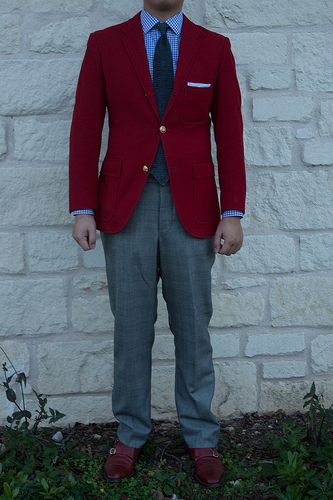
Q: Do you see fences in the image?
A: No, there are no fences.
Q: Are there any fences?
A: No, there are no fences.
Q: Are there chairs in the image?
A: No, there are no chairs.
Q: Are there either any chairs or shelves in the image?
A: No, there are no chairs or shelves.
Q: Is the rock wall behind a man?
A: Yes, the wall is behind a man.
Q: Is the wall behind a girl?
A: No, the wall is behind a man.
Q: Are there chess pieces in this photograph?
A: No, there are no chess pieces.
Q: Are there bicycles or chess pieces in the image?
A: No, there are no chess pieces or bicycles.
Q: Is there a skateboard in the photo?
A: No, there are no skateboards.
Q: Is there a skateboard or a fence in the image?
A: No, there are no skateboards or fences.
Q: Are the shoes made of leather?
A: Yes, the shoes are made of leather.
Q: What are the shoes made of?
A: The shoes are made of leather.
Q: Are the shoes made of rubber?
A: No, the shoes are made of leather.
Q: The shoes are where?
A: The shoes are on the ground.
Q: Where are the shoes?
A: The shoes are on the ground.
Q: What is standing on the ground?
A: The shoes are standing on the ground.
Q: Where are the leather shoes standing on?
A: The shoes are standing on the ground.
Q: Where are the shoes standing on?
A: The shoes are standing on the ground.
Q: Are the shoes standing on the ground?
A: Yes, the shoes are standing on the ground.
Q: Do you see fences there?
A: No, there are no fences.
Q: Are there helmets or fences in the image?
A: No, there are no fences or helmets.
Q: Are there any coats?
A: Yes, there is a coat.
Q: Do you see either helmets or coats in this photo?
A: Yes, there is a coat.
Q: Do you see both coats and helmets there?
A: No, there is a coat but no helmets.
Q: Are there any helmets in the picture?
A: No, there are no helmets.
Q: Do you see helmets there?
A: No, there are no helmets.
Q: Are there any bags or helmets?
A: No, there are no helmets or bags.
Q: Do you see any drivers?
A: No, there are no drivers.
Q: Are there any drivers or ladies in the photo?
A: No, there are no drivers or ladies.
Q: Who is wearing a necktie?
A: The man is wearing a necktie.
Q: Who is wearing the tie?
A: The man is wearing a necktie.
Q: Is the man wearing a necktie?
A: Yes, the man is wearing a necktie.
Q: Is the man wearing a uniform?
A: No, the man is wearing a necktie.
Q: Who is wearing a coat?
A: The man is wearing a coat.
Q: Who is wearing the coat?
A: The man is wearing a coat.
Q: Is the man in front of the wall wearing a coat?
A: Yes, the man is wearing a coat.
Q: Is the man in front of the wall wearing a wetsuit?
A: No, the man is wearing a coat.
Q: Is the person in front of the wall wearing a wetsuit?
A: No, the man is wearing a coat.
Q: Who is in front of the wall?
A: The man is in front of the wall.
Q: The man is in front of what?
A: The man is in front of the wall.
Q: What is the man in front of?
A: The man is in front of the wall.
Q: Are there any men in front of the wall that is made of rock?
A: Yes, there is a man in front of the wall.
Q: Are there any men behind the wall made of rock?
A: No, the man is in front of the wall.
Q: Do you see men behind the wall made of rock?
A: No, the man is in front of the wall.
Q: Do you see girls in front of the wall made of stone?
A: No, there is a man in front of the wall.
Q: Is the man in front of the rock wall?
A: Yes, the man is in front of the wall.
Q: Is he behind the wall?
A: No, the man is in front of the wall.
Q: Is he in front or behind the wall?
A: The man is in front of the wall.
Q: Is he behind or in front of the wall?
A: The man is in front of the wall.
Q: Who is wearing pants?
A: The man is wearing pants.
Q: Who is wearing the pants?
A: The man is wearing pants.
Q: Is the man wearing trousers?
A: Yes, the man is wearing trousers.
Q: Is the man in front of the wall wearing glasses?
A: No, the man is wearing trousers.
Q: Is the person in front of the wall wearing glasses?
A: No, the man is wearing trousers.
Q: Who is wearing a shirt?
A: The man is wearing a shirt.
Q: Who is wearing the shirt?
A: The man is wearing a shirt.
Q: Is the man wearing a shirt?
A: Yes, the man is wearing a shirt.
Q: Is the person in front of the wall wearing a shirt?
A: Yes, the man is wearing a shirt.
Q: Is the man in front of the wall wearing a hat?
A: No, the man is wearing a shirt.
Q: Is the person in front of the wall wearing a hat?
A: No, the man is wearing a shirt.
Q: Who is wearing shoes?
A: The man is wearing shoes.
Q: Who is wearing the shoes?
A: The man is wearing shoes.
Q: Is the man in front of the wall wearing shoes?
A: Yes, the man is wearing shoes.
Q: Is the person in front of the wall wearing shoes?
A: Yes, the man is wearing shoes.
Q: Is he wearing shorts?
A: No, the man is wearing shoes.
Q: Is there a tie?
A: Yes, there is a tie.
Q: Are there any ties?
A: Yes, there is a tie.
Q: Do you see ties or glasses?
A: Yes, there is a tie.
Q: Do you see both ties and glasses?
A: No, there is a tie but no glasses.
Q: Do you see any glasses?
A: No, there are no glasses.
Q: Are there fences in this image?
A: No, there are no fences.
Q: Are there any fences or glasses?
A: No, there are no fences or glasses.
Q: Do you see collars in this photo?
A: Yes, there is a collar.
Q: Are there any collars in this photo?
A: Yes, there is a collar.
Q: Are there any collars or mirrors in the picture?
A: Yes, there is a collar.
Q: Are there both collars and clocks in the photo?
A: No, there is a collar but no clocks.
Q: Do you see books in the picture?
A: No, there are no books.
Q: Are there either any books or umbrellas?
A: No, there are no books or umbrellas.